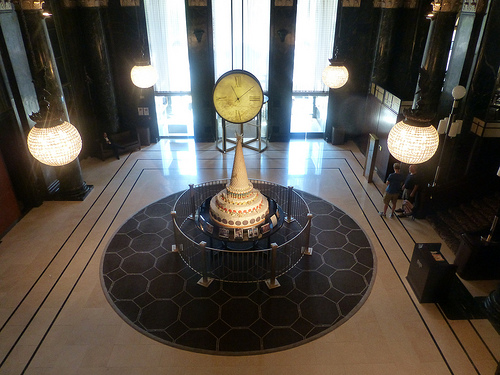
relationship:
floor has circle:
[1, 124, 500, 373] [101, 179, 380, 353]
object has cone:
[207, 184, 270, 227] [227, 137, 252, 189]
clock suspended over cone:
[212, 70, 267, 124] [227, 137, 252, 189]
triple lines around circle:
[2, 146, 499, 374] [101, 179, 380, 353]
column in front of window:
[18, 2, 94, 202] [145, 2, 197, 139]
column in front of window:
[395, 2, 463, 219] [289, 2, 341, 141]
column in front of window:
[374, 4, 394, 98] [211, 2, 270, 143]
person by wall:
[377, 164, 404, 218] [359, 1, 491, 201]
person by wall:
[398, 165, 419, 220] [359, 1, 491, 201]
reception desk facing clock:
[406, 241, 456, 304] [212, 70, 267, 124]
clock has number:
[212, 70, 267, 124] [233, 73, 244, 87]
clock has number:
[212, 70, 267, 124] [248, 94, 262, 102]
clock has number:
[212, 70, 267, 124] [233, 108, 246, 122]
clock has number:
[212, 70, 267, 124] [216, 92, 230, 103]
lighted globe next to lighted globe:
[124, 58, 161, 89] [320, 58, 349, 91]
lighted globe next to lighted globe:
[24, 124, 87, 165] [387, 114, 440, 164]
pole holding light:
[433, 98, 457, 194] [451, 87, 467, 99]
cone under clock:
[227, 137, 252, 189] [212, 70, 267, 124]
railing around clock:
[168, 176, 314, 283] [212, 70, 267, 124]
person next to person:
[377, 164, 404, 218] [398, 165, 419, 220]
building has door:
[1, 1, 500, 373] [1, 146, 26, 233]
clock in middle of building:
[212, 70, 267, 124] [1, 1, 500, 373]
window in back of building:
[145, 2, 197, 139] [1, 1, 500, 373]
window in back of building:
[289, 2, 341, 141] [1, 1, 500, 373]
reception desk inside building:
[406, 241, 456, 304] [1, 1, 500, 373]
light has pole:
[451, 87, 467, 99] [433, 98, 457, 194]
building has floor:
[1, 1, 500, 373] [1, 124, 500, 373]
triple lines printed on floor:
[2, 146, 499, 374] [1, 124, 500, 373]